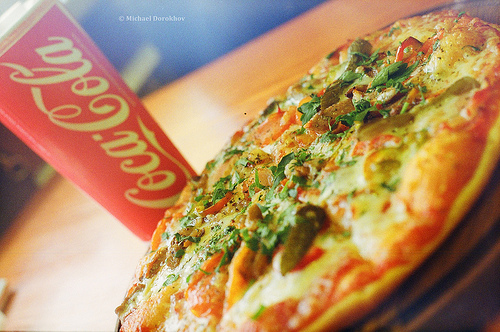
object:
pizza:
[309, 131, 406, 240]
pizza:
[114, 13, 499, 331]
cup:
[0, 0, 191, 244]